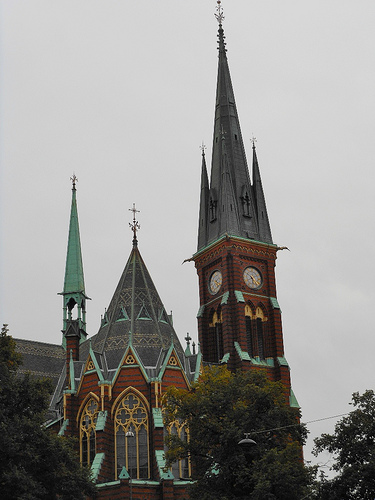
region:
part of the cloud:
[314, 127, 360, 168]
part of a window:
[136, 455, 151, 466]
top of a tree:
[213, 382, 251, 423]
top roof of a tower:
[116, 278, 147, 316]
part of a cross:
[121, 195, 140, 225]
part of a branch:
[198, 452, 218, 475]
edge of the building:
[91, 432, 107, 454]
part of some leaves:
[311, 437, 336, 457]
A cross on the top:
[110, 180, 148, 246]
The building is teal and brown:
[73, 323, 165, 477]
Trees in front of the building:
[136, 370, 302, 486]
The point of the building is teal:
[4, 177, 119, 387]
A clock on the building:
[222, 257, 269, 303]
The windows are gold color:
[104, 384, 144, 493]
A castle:
[48, 25, 293, 488]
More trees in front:
[0, 317, 37, 490]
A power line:
[232, 405, 360, 457]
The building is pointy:
[76, 338, 177, 384]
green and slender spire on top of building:
[47, 141, 92, 354]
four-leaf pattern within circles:
[108, 384, 150, 426]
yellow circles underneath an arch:
[105, 382, 152, 431]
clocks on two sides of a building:
[199, 237, 265, 298]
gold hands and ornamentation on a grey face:
[235, 260, 266, 290]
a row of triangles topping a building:
[71, 330, 191, 371]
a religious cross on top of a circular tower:
[86, 195, 192, 465]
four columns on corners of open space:
[45, 285, 90, 331]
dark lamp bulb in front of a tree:
[191, 375, 302, 485]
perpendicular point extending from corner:
[263, 237, 296, 256]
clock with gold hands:
[239, 265, 264, 291]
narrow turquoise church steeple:
[61, 174, 91, 342]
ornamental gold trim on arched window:
[108, 384, 155, 485]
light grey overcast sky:
[23, 31, 175, 152]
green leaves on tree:
[163, 357, 298, 498]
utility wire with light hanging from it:
[180, 400, 364, 458]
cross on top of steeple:
[124, 198, 147, 246]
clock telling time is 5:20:
[240, 263, 267, 296]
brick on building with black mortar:
[220, 239, 241, 293]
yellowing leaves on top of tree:
[154, 356, 291, 430]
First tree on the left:
[0, 322, 97, 498]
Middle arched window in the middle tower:
[109, 386, 156, 480]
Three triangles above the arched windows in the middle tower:
[78, 345, 189, 381]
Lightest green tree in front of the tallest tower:
[162, 360, 314, 498]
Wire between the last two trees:
[244, 412, 350, 436]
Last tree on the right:
[310, 389, 374, 499]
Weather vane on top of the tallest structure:
[214, 0, 225, 23]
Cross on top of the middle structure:
[126, 202, 143, 219]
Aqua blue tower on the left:
[61, 189, 87, 345]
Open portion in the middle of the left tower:
[65, 298, 83, 319]